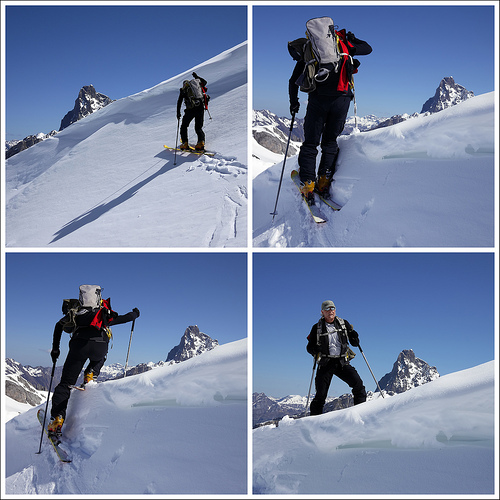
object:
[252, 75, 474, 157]
mountains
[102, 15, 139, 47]
sky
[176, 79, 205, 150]
skier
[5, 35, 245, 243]
mountain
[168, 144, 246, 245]
ski marks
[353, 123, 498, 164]
ski marks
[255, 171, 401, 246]
ski marks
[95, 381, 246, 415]
ski marks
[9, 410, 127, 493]
ski marks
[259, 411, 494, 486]
ski marks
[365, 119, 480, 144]
patches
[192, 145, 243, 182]
snow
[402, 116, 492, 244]
snow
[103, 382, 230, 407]
snow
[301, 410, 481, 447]
snow